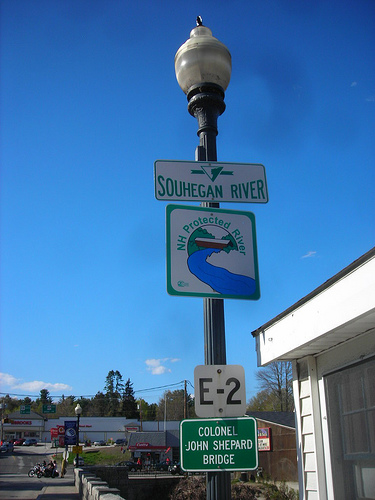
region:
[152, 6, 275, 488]
Large street light post with multiple signs on it.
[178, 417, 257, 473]
Green and white sign that reads Colenel John Shepard Bridge.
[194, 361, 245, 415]
Square white and black sign that reads 'E-2'.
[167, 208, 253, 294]
Large square sign that reads 'NH Protected River'.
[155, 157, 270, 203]
White rectangular sign that reads 'Souhegan River'.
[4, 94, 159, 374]
Forecast is clear blue skies.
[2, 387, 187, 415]
Assorted green trees in the distance.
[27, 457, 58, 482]
Motorcyclists driving on the road.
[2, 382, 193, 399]
Telephone wires spanning across picture.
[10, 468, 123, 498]
A paved road bridge.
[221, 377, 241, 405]
number on the sign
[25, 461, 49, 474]
motorcycles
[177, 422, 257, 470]
the sign is green and white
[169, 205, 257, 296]
a sign on the pole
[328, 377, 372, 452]
a window in the building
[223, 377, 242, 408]
the 2 is black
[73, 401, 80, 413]
a street light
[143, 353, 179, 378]
white clouds in the sky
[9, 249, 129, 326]
the sky is clear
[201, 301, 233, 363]
a pole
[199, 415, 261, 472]
A street sign.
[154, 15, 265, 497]
A tall lamp post with street signs.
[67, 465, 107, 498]
A stone wall.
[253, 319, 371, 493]
A white building with siding.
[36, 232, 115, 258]
Beautiful blue skies.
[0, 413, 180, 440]
A shopping center.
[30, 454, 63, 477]
Motorcycles cross the street.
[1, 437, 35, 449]
Cars in a parking lot.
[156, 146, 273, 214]
white and green sign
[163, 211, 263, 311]
blue and white sign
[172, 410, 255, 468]
white and green bridge sign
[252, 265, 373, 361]
white awning over house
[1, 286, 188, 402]
blue and white sky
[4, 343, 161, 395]
few clouds in sky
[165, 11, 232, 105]
light on top of pole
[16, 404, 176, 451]
red and white store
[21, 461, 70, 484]
couple people on bikes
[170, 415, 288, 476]
a sign for a bridge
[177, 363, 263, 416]
a sign reading e 2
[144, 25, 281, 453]
a light post with signs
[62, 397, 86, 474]
a flag hanging from pole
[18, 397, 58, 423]
green road sign above store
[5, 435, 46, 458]
cars parked in front of store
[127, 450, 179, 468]
people outside of a store